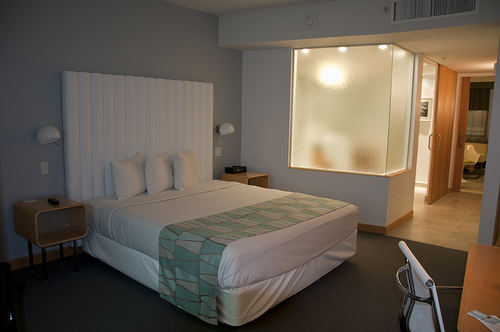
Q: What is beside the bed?
A: A modern night stand.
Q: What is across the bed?
A: A green and grey bedspread.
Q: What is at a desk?
A: A chair.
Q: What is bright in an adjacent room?
A: Lighting.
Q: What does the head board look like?
A: Tall, white, an modern.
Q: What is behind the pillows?
A: A white headboard.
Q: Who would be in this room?
A: A traveler.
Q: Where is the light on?
A: In the bathroom.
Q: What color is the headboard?
A: White.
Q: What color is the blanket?
A: Blue.